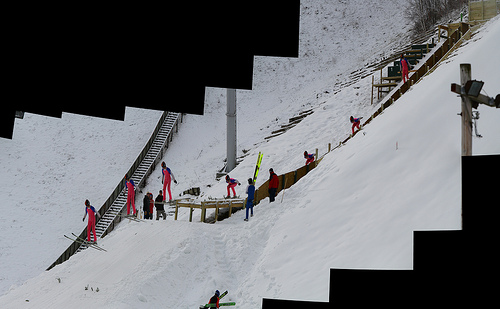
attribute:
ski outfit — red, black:
[400, 62, 410, 80]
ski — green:
[205, 299, 235, 307]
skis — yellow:
[252, 148, 261, 183]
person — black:
[102, 164, 156, 204]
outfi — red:
[385, 46, 439, 68]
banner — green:
[251, 146, 266, 186]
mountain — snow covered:
[0, 7, 497, 307]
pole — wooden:
[452, 60, 484, 151]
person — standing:
[242, 174, 259, 216]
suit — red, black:
[83, 204, 97, 242]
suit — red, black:
[121, 180, 135, 213]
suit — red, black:
[161, 168, 175, 202]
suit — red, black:
[226, 179, 238, 196]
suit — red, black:
[398, 61, 410, 81]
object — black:
[465, 78, 482, 95]